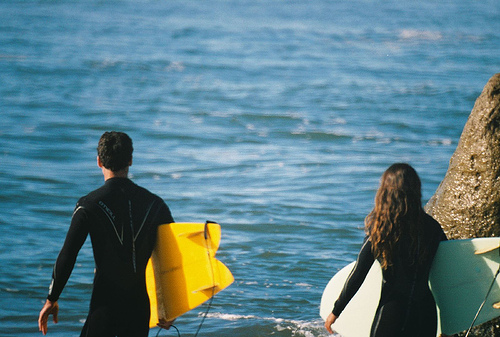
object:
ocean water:
[1, 2, 484, 333]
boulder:
[419, 71, 500, 238]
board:
[146, 219, 233, 331]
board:
[323, 232, 500, 337]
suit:
[50, 185, 181, 336]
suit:
[333, 202, 453, 337]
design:
[94, 193, 166, 275]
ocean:
[0, 0, 500, 337]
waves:
[204, 104, 365, 209]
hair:
[363, 162, 431, 271]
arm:
[327, 242, 378, 319]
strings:
[202, 219, 221, 306]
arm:
[430, 216, 450, 241]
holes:
[466, 153, 481, 166]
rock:
[427, 68, 497, 231]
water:
[0, 0, 485, 333]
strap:
[200, 219, 222, 296]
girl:
[326, 159, 451, 336]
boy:
[44, 122, 187, 336]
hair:
[94, 129, 138, 174]